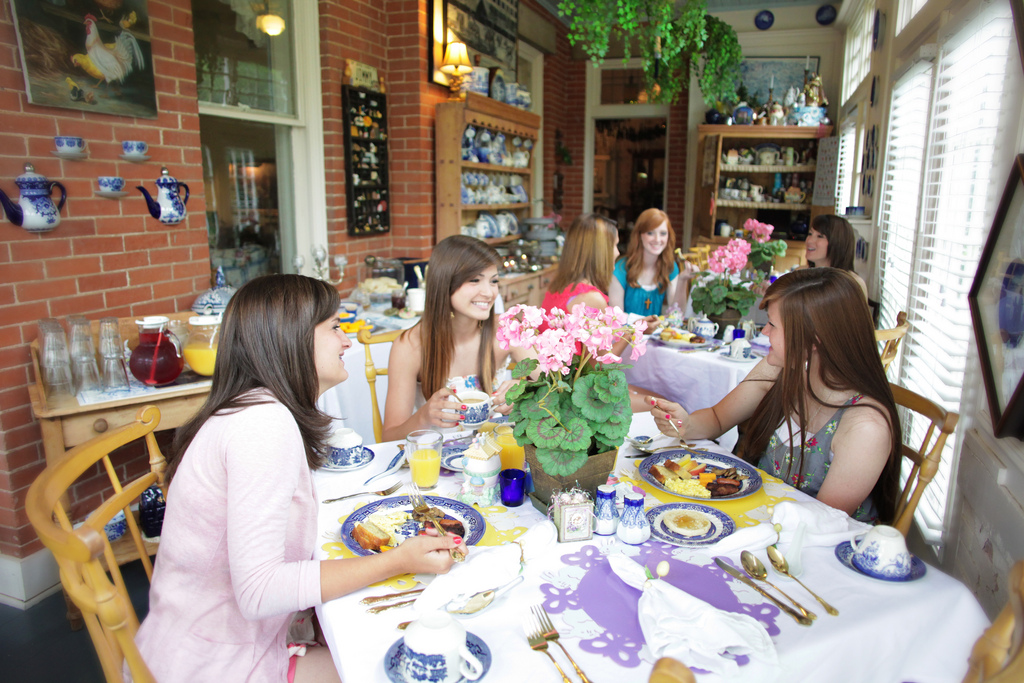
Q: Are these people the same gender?
A: Yes, all the people are female.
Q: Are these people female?
A: Yes, all the people are female.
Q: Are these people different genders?
A: No, all the people are female.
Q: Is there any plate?
A: Yes, there is a plate.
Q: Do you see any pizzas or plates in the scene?
A: Yes, there is a plate.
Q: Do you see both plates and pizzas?
A: No, there is a plate but no pizzas.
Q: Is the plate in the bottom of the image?
A: Yes, the plate is in the bottom of the image.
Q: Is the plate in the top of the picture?
A: No, the plate is in the bottom of the image.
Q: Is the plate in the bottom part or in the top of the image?
A: The plate is in the bottom of the image.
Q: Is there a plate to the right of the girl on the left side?
A: Yes, there is a plate to the right of the girl.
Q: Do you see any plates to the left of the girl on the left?
A: No, the plate is to the right of the girl.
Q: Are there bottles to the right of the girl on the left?
A: No, there is a plate to the right of the girl.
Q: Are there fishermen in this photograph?
A: No, there are no fishermen.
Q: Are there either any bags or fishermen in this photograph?
A: No, there are no fishermen or bags.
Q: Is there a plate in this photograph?
A: Yes, there is a plate.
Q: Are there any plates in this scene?
A: Yes, there is a plate.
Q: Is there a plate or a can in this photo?
A: Yes, there is a plate.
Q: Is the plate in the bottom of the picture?
A: Yes, the plate is in the bottom of the image.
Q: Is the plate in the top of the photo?
A: No, the plate is in the bottom of the image.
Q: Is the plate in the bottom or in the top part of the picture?
A: The plate is in the bottom of the image.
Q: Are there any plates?
A: Yes, there is a plate.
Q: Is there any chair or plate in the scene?
A: Yes, there is a plate.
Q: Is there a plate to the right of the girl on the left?
A: Yes, there is a plate to the right of the girl.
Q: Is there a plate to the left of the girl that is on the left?
A: No, the plate is to the right of the girl.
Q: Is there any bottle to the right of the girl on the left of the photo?
A: No, there is a plate to the right of the girl.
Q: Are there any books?
A: No, there are no books.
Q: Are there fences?
A: No, there are no fences.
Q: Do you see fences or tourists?
A: No, there are no fences or tourists.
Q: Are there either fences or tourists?
A: No, there are no fences or tourists.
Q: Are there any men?
A: No, there are no men.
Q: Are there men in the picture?
A: No, there are no men.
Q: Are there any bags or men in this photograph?
A: No, there are no men or bags.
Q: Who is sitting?
A: The girl is sitting.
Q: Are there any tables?
A: Yes, there is a table.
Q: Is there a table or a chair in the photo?
A: Yes, there is a table.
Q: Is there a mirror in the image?
A: No, there are no mirrors.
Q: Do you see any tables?
A: Yes, there is a table.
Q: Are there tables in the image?
A: Yes, there is a table.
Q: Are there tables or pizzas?
A: Yes, there is a table.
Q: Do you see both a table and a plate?
A: Yes, there are both a table and a plate.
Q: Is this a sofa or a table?
A: This is a table.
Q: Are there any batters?
A: No, there are no batters.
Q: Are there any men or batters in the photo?
A: No, there are no batters or men.